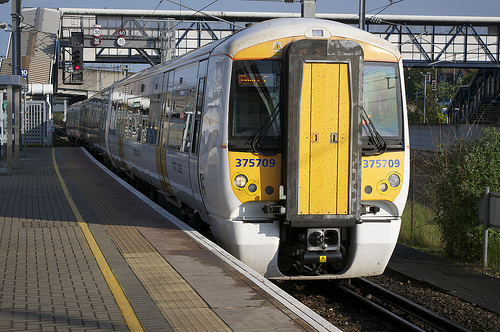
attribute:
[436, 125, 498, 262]
plant — green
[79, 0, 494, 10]
sky — blue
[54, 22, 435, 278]
track — railway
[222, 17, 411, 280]
train front — white, yellow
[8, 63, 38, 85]
sign — blue, white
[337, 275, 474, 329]
rails — metal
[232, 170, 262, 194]
light — head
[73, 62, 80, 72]
light — glowing, red